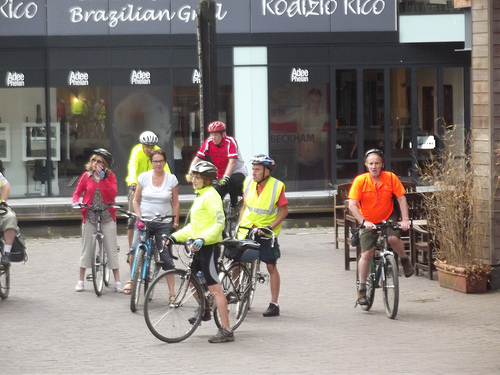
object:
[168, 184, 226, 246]
tops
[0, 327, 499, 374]
surface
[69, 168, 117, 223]
sweater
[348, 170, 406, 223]
orange shirt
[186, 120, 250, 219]
biker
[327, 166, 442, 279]
wooden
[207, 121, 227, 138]
helmet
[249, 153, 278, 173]
helmet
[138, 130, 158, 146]
helmet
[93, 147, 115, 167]
helmet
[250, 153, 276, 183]
head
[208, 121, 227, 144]
head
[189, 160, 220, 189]
head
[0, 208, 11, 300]
bicycles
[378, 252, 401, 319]
wheel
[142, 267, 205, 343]
wheel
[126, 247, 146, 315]
wheel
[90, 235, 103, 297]
wheel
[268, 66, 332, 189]
advertising poster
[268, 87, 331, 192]
david beckham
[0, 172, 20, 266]
bikers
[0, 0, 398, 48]
awning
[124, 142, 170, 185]
jacket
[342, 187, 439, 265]
table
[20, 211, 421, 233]
water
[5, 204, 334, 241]
canal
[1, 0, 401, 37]
sign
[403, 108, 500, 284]
plant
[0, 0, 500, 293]
building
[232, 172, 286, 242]
neon jacket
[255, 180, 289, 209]
orange t-shirt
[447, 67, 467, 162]
glass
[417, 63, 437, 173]
glass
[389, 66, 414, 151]
glass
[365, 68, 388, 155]
glass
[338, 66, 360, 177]
glass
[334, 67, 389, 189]
furniture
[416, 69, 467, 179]
furniture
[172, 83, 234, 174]
furniture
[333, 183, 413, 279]
chairs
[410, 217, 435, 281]
chairs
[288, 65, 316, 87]
name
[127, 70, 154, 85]
name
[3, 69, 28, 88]
name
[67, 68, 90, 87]
name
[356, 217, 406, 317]
bicycle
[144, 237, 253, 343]
bicycle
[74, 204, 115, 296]
bicycle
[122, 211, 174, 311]
bicycle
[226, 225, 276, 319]
bicycle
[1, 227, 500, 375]
ground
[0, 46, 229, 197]
window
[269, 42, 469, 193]
window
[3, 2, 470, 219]
storefront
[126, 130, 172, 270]
bikes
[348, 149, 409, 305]
biker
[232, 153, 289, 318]
biker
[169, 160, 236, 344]
biker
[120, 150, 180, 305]
biker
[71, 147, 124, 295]
biker